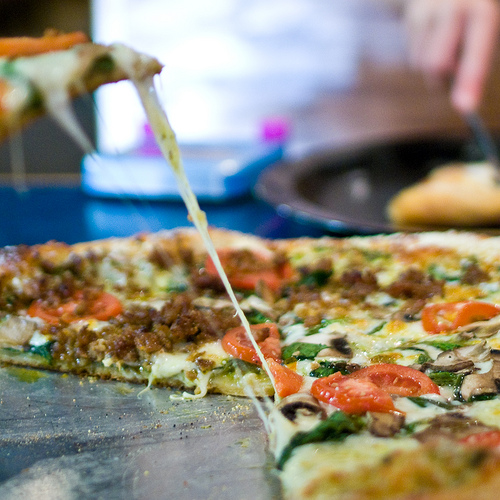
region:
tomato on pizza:
[318, 374, 394, 410]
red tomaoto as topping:
[364, 360, 428, 395]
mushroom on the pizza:
[283, 391, 324, 422]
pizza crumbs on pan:
[150, 407, 213, 448]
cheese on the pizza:
[356, 333, 386, 353]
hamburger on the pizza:
[129, 320, 162, 351]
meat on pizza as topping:
[164, 306, 209, 339]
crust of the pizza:
[377, 466, 457, 498]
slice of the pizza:
[0, 25, 155, 141]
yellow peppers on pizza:
[381, 318, 407, 338]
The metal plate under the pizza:
[31, 389, 219, 484]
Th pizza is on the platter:
[36, 222, 499, 497]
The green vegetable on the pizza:
[280, 405, 360, 455]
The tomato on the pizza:
[318, 359, 417, 413]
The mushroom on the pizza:
[439, 342, 486, 372]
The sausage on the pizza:
[110, 297, 213, 344]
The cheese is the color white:
[170, 192, 288, 407]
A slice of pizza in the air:
[3, 26, 188, 141]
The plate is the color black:
[258, 155, 383, 230]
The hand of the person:
[397, 0, 499, 117]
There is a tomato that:
[343, 363, 390, 428]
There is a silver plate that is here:
[158, 413, 183, 450]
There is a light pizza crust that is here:
[226, 377, 247, 398]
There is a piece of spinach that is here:
[290, 334, 312, 364]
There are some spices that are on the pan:
[170, 398, 199, 445]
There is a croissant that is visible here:
[412, 172, 476, 229]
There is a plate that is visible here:
[309, 190, 331, 246]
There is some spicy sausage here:
[158, 313, 180, 345]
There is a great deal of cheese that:
[183, 207, 250, 309]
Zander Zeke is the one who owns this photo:
[123, 168, 348, 457]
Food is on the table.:
[0, 0, 496, 498]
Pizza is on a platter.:
[0, 215, 497, 496]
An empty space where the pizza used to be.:
[1, 365, 267, 498]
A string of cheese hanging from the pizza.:
[125, 65, 295, 410]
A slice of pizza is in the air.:
[0, 26, 166, 133]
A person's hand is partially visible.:
[400, 0, 491, 111]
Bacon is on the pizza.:
[76, 297, 221, 352]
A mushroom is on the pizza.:
[277, 385, 319, 425]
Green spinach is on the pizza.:
[281, 335, 316, 356]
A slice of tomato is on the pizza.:
[310, 361, 437, 414]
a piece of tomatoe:
[336, 360, 418, 422]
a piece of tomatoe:
[230, 316, 281, 355]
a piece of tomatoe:
[62, 289, 119, 316]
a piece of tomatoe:
[219, 245, 276, 292]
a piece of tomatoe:
[432, 298, 465, 348]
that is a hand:
[430, 5, 482, 55]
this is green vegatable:
[300, 413, 340, 449]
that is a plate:
[296, 160, 341, 205]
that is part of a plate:
[168, 420, 205, 452]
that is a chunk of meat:
[157, 306, 184, 361]